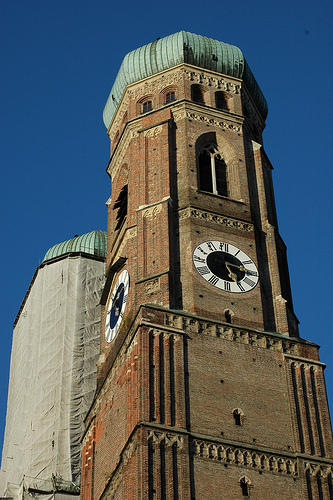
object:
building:
[0, 230, 107, 500]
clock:
[192, 240, 259, 293]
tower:
[77, 29, 333, 500]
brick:
[151, 150, 172, 178]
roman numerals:
[193, 254, 205, 264]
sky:
[0, 4, 333, 474]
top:
[38, 230, 106, 265]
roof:
[102, 29, 269, 131]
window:
[232, 408, 245, 426]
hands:
[225, 262, 237, 282]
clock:
[104, 269, 129, 343]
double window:
[197, 141, 230, 197]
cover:
[0, 257, 105, 500]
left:
[77, 173, 139, 499]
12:
[219, 242, 229, 252]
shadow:
[242, 133, 275, 332]